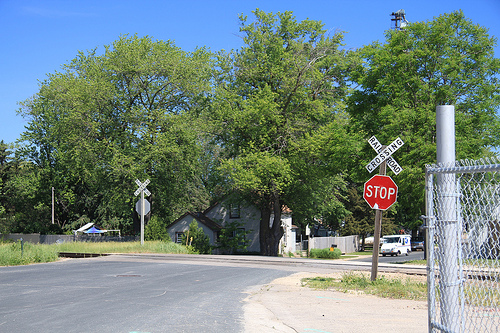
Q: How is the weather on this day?
A: It is clear.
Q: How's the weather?
A: It is clear.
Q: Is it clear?
A: Yes, it is clear.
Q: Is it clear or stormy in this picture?
A: It is clear.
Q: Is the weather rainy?
A: No, it is clear.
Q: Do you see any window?
A: Yes, there are windows.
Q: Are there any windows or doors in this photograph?
A: Yes, there are windows.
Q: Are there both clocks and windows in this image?
A: No, there are windows but no clocks.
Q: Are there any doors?
A: No, there are no doors.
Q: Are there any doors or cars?
A: No, there are no doors or cars.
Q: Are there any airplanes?
A: No, there are no airplanes.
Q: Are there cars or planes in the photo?
A: No, there are no planes or cars.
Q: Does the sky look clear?
A: Yes, the sky is clear.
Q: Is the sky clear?
A: Yes, the sky is clear.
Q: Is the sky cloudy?
A: No, the sky is clear.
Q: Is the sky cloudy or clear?
A: The sky is clear.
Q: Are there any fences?
A: Yes, there is a fence.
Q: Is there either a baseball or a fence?
A: Yes, there is a fence.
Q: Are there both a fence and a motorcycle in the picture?
A: No, there is a fence but no motorcycles.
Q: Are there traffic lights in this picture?
A: No, there are no traffic lights.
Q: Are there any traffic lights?
A: No, there are no traffic lights.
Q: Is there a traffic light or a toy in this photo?
A: No, there are no traffic lights or toys.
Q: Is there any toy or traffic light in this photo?
A: No, there are no traffic lights or toys.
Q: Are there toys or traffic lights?
A: No, there are no traffic lights or toys.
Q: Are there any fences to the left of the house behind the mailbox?
A: Yes, there is a fence to the left of the house.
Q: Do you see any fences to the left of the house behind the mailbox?
A: Yes, there is a fence to the left of the house.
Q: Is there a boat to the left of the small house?
A: No, there is a fence to the left of the house.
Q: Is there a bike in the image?
A: No, there are no bikes.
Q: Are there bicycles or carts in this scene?
A: No, there are no bicycles or carts.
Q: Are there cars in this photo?
A: No, there are no cars.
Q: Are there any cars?
A: No, there are no cars.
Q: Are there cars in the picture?
A: No, there are no cars.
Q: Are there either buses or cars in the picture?
A: No, there are no cars or buses.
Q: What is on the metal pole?
A: The sign is on the pole.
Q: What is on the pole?
A: The sign is on the pole.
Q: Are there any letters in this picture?
A: Yes, there are letters.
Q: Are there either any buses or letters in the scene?
A: Yes, there are letters.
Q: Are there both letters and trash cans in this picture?
A: No, there are letters but no trash cans.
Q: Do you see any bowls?
A: No, there are no bowls.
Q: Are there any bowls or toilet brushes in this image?
A: No, there are no bowls or toilet brushes.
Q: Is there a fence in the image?
A: Yes, there is a fence.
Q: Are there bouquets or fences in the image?
A: Yes, there is a fence.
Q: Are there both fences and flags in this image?
A: No, there is a fence but no flags.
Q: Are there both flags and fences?
A: No, there is a fence but no flags.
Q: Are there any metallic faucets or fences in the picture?
A: Yes, there is a metal fence.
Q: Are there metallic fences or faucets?
A: Yes, there is a metal fence.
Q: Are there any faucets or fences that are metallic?
A: Yes, the fence is metallic.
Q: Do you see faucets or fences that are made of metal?
A: Yes, the fence is made of metal.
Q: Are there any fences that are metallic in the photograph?
A: Yes, there is a metal fence.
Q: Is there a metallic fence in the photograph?
A: Yes, there is a metal fence.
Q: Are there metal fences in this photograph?
A: Yes, there is a metal fence.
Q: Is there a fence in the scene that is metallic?
A: Yes, there is a fence that is metallic.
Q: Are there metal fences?
A: Yes, there is a fence that is made of metal.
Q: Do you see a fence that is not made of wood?
A: Yes, there is a fence that is made of metal.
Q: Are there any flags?
A: No, there are no flags.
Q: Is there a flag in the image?
A: No, there are no flags.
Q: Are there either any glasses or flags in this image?
A: No, there are no flags or glasses.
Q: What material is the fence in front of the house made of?
A: The fence is made of metal.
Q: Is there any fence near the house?
A: Yes, there is a fence near the house.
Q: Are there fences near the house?
A: Yes, there is a fence near the house.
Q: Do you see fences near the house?
A: Yes, there is a fence near the house.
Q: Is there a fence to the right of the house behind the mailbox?
A: Yes, there is a fence to the right of the house.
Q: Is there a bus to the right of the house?
A: No, there is a fence to the right of the house.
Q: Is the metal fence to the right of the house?
A: Yes, the fence is to the right of the house.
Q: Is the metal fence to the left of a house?
A: No, the fence is to the right of a house.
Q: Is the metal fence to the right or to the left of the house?
A: The fence is to the right of the house.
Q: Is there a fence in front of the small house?
A: Yes, there is a fence in front of the house.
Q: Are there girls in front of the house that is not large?
A: No, there is a fence in front of the house.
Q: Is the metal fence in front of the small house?
A: Yes, the fence is in front of the house.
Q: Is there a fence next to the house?
A: Yes, there is a fence next to the house.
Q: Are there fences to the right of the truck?
A: Yes, there is a fence to the right of the truck.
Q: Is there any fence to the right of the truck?
A: Yes, there is a fence to the right of the truck.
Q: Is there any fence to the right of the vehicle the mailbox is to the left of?
A: Yes, there is a fence to the right of the truck.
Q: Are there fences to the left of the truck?
A: No, the fence is to the right of the truck.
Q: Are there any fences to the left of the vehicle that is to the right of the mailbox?
A: No, the fence is to the right of the truck.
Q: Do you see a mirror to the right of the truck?
A: No, there is a fence to the right of the truck.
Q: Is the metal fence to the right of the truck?
A: Yes, the fence is to the right of the truck.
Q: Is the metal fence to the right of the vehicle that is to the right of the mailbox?
A: Yes, the fence is to the right of the truck.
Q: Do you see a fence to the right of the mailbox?
A: Yes, there is a fence to the right of the mailbox.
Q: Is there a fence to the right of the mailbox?
A: Yes, there is a fence to the right of the mailbox.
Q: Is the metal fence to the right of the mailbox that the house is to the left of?
A: Yes, the fence is to the right of the mailbox.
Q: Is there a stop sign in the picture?
A: Yes, there is a stop sign.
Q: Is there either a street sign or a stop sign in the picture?
A: Yes, there is a stop sign.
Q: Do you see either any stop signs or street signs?
A: Yes, there is a stop sign.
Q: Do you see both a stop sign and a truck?
A: Yes, there are both a stop sign and a truck.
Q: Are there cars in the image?
A: No, there are no cars.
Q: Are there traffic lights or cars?
A: No, there are no cars or traffic lights.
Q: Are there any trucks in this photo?
A: Yes, there is a truck.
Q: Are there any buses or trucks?
A: Yes, there is a truck.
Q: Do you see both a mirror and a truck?
A: No, there is a truck but no mirrors.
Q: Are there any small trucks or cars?
A: Yes, there is a small truck.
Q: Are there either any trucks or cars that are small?
A: Yes, the truck is small.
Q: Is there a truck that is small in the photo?
A: Yes, there is a small truck.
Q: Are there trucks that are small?
A: Yes, there is a truck that is small.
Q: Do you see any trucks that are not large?
A: Yes, there is a small truck.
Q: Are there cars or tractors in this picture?
A: No, there are no cars or tractors.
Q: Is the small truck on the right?
A: Yes, the truck is on the right of the image.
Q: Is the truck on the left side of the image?
A: No, the truck is on the right of the image.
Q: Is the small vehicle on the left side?
A: No, the truck is on the right of the image.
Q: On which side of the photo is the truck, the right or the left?
A: The truck is on the right of the image.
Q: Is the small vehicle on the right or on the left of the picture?
A: The truck is on the right of the image.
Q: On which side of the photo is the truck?
A: The truck is on the right of the image.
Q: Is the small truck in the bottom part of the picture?
A: Yes, the truck is in the bottom of the image.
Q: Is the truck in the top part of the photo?
A: No, the truck is in the bottom of the image.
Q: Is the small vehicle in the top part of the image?
A: No, the truck is in the bottom of the image.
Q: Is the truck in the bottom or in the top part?
A: The truck is in the bottom of the image.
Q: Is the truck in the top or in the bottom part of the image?
A: The truck is in the bottom of the image.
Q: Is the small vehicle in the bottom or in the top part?
A: The truck is in the bottom of the image.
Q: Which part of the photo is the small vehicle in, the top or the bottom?
A: The truck is in the bottom of the image.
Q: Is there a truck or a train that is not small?
A: No, there is a truck but it is small.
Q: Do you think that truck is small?
A: Yes, the truck is small.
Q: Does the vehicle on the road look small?
A: Yes, the truck is small.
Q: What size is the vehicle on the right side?
A: The truck is small.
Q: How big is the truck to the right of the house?
A: The truck is small.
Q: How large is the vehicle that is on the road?
A: The truck is small.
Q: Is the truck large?
A: No, the truck is small.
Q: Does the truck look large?
A: No, the truck is small.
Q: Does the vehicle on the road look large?
A: No, the truck is small.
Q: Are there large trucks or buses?
A: No, there is a truck but it is small.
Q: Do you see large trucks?
A: No, there is a truck but it is small.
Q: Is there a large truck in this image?
A: No, there is a truck but it is small.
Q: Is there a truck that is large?
A: No, there is a truck but it is small.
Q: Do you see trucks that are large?
A: No, there is a truck but it is small.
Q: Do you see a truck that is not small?
A: No, there is a truck but it is small.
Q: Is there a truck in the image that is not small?
A: No, there is a truck but it is small.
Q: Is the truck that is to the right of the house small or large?
A: The truck is small.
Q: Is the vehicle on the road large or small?
A: The truck is small.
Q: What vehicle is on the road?
A: The vehicle is a truck.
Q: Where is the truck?
A: The truck is on the road.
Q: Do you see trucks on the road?
A: Yes, there is a truck on the road.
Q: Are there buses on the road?
A: No, there is a truck on the road.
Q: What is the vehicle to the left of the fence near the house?
A: The vehicle is a truck.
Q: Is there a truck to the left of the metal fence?
A: Yes, there is a truck to the left of the fence.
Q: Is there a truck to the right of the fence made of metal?
A: No, the truck is to the left of the fence.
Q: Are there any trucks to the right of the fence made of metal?
A: No, the truck is to the left of the fence.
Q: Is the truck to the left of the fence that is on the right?
A: Yes, the truck is to the left of the fence.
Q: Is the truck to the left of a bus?
A: No, the truck is to the left of the fence.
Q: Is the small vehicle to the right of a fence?
A: No, the truck is to the left of a fence.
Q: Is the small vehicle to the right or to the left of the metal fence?
A: The truck is to the left of the fence.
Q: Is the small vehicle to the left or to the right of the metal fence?
A: The truck is to the left of the fence.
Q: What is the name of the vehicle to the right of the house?
A: The vehicle is a truck.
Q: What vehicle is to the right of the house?
A: The vehicle is a truck.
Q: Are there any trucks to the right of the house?
A: Yes, there is a truck to the right of the house.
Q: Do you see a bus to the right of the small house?
A: No, there is a truck to the right of the house.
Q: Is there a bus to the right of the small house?
A: No, there is a truck to the right of the house.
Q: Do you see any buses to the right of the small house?
A: No, there is a truck to the right of the house.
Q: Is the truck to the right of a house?
A: Yes, the truck is to the right of a house.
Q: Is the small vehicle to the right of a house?
A: Yes, the truck is to the right of a house.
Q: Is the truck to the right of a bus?
A: No, the truck is to the right of a house.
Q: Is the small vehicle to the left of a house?
A: No, the truck is to the right of a house.